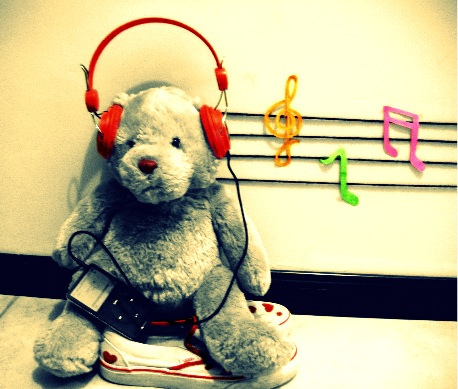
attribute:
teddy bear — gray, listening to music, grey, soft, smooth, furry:
[34, 87, 295, 381]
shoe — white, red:
[146, 301, 292, 340]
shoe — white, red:
[99, 328, 300, 388]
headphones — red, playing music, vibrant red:
[79, 16, 232, 162]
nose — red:
[137, 158, 158, 175]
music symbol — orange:
[261, 75, 304, 169]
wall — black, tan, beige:
[0, 0, 457, 279]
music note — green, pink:
[319, 148, 359, 206]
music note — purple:
[382, 103, 426, 172]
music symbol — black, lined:
[217, 112, 458, 189]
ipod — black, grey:
[67, 264, 158, 344]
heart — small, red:
[103, 350, 118, 364]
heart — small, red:
[262, 300, 276, 313]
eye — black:
[125, 137, 137, 148]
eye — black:
[171, 137, 181, 148]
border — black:
[1, 251, 457, 323]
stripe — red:
[97, 356, 243, 379]